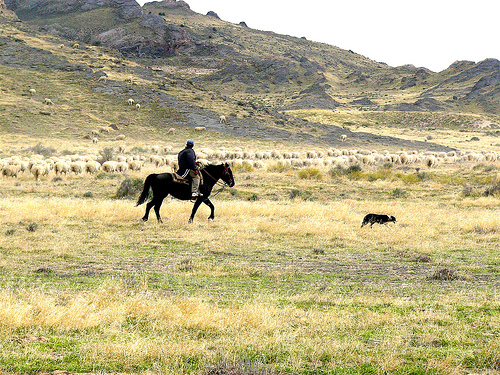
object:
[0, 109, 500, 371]
grass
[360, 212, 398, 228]
dog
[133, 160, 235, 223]
horse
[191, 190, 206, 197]
shoes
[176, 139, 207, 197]
man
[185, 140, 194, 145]
hat